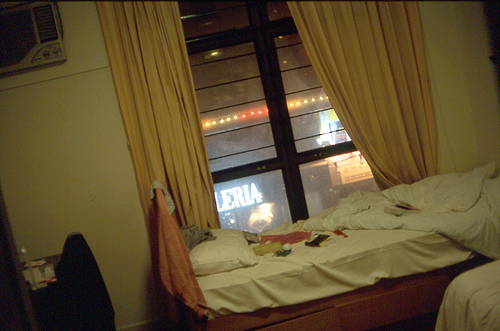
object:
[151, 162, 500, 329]
bed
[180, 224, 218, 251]
grey shirt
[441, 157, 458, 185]
ground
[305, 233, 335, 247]
book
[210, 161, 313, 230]
window pane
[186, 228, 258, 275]
pillow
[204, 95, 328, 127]
lights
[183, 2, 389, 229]
pane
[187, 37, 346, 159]
bar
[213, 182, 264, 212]
sign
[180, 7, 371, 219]
bar window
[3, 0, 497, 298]
wall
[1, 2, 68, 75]
conditioner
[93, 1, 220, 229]
curtain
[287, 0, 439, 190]
curtain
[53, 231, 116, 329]
chair